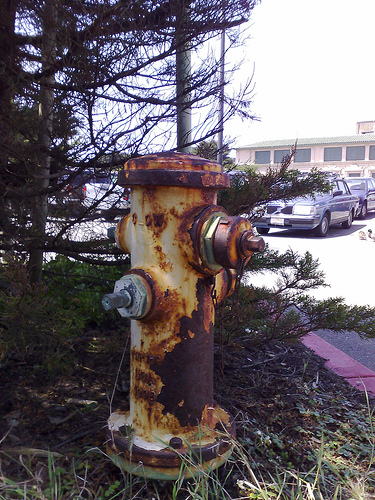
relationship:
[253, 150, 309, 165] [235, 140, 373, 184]
window on building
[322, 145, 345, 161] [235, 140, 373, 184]
window on building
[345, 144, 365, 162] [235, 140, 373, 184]
window on building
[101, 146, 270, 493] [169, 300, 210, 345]
fire hydrant has much rust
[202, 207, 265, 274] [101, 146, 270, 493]
valve on fire hydrant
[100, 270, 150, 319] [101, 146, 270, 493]
valve on fire hydrant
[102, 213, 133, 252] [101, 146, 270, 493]
valve on fire hydrant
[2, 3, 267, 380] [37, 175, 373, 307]
tree in parking lot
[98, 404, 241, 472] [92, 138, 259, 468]
bottom of hydrant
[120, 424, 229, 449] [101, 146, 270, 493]
bolts on fire hydrant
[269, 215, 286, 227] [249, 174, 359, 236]
licence plate on car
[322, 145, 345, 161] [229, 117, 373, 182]
window on building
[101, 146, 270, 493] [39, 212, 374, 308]
fire hydrant on road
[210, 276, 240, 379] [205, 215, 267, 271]
chain from plug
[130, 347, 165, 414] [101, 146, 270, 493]
letters on fire hydrant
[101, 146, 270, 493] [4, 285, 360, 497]
fire hydrant in ground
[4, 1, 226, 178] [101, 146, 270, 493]
trees behind fire hydrant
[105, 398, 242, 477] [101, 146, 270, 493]
base of fire hydrant